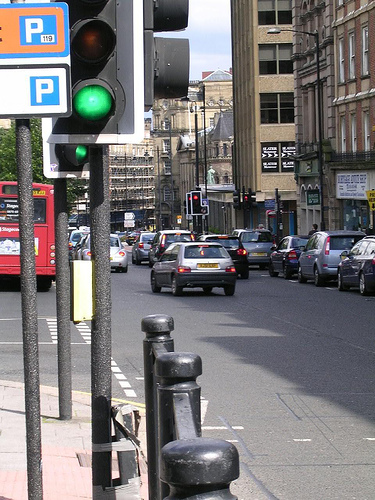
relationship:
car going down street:
[151, 240, 237, 295] [0, 250, 373, 498]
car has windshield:
[151, 240, 237, 295] [182, 243, 229, 261]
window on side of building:
[259, 90, 295, 126] [232, 0, 296, 232]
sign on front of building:
[260, 143, 296, 175] [232, 0, 296, 232]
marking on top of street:
[199, 425, 247, 430] [0, 250, 373, 498]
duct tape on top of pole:
[91, 440, 139, 453] [92, 146, 113, 499]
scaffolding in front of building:
[110, 152, 155, 216] [108, 118, 154, 232]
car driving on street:
[151, 240, 237, 295] [0, 250, 373, 498]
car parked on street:
[297, 230, 366, 288] [0, 250, 373, 498]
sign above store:
[334, 172, 369, 199] [336, 198, 374, 232]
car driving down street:
[151, 240, 237, 295] [0, 250, 373, 498]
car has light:
[151, 240, 237, 295] [178, 267, 191, 275]